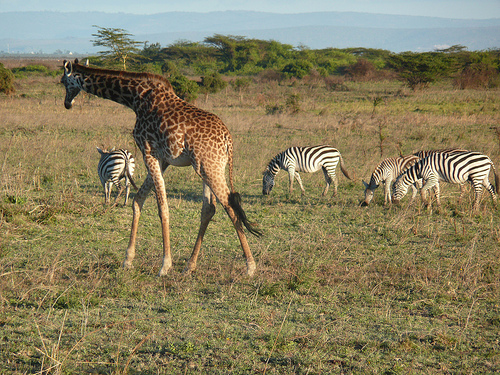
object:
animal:
[95, 145, 138, 207]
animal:
[60, 58, 262, 278]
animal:
[261, 145, 355, 198]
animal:
[391, 151, 499, 211]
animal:
[361, 155, 422, 212]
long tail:
[490, 160, 499, 193]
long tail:
[126, 159, 139, 191]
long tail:
[228, 134, 262, 239]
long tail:
[339, 155, 352, 179]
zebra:
[411, 148, 467, 159]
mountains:
[0, 9, 500, 57]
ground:
[295, 213, 498, 373]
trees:
[0, 25, 499, 116]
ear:
[361, 179, 369, 187]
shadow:
[80, 179, 264, 204]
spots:
[151, 106, 182, 138]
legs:
[120, 160, 171, 278]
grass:
[39, 169, 497, 374]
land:
[15, 102, 500, 372]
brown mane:
[72, 64, 171, 88]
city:
[0, 45, 95, 57]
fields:
[0, 69, 499, 375]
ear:
[62, 59, 73, 77]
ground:
[278, 218, 418, 358]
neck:
[76, 60, 161, 114]